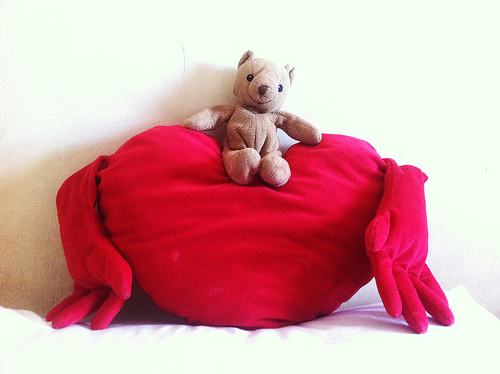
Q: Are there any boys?
A: No, there are no boys.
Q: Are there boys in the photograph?
A: No, there are no boys.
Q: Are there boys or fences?
A: No, there are no boys or fences.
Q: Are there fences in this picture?
A: No, there are no fences.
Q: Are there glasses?
A: No, there are no glasses.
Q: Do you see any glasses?
A: No, there are no glasses.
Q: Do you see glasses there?
A: No, there are no glasses.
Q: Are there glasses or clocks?
A: No, there are no glasses or clocks.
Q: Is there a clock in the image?
A: No, there are no clocks.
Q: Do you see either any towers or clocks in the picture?
A: No, there are no clocks or towers.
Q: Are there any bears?
A: Yes, there is a bear.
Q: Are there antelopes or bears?
A: Yes, there is a bear.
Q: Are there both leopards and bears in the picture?
A: No, there is a bear but no leopards.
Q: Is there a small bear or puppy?
A: Yes, there is a small bear.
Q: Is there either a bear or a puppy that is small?
A: Yes, the bear is small.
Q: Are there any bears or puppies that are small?
A: Yes, the bear is small.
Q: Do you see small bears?
A: Yes, there is a small bear.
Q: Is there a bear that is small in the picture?
A: Yes, there is a small bear.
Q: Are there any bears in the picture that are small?
A: Yes, there is a bear that is small.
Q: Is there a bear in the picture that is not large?
A: Yes, there is a small bear.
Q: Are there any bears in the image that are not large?
A: Yes, there is a small bear.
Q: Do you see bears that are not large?
A: Yes, there is a small bear.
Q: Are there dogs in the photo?
A: No, there are no dogs.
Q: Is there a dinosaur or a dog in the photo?
A: No, there are no dogs or dinosaurs.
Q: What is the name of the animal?
A: The animal is a bear.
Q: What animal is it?
A: The animal is a bear.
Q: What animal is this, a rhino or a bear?
A: That is a bear.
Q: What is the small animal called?
A: The animal is a bear.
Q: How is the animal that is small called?
A: The animal is a bear.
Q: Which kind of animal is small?
A: The animal is a bear.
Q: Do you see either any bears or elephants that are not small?
A: No, there is a bear but it is small.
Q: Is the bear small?
A: Yes, the bear is small.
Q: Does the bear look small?
A: Yes, the bear is small.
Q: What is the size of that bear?
A: The bear is small.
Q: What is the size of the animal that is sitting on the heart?
A: The bear is small.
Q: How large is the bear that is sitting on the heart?
A: The bear is small.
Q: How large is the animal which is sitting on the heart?
A: The bear is small.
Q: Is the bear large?
A: No, the bear is small.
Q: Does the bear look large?
A: No, the bear is small.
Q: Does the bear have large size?
A: No, the bear is small.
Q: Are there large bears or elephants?
A: No, there is a bear but it is small.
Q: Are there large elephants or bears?
A: No, there is a bear but it is small.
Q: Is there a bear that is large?
A: No, there is a bear but it is small.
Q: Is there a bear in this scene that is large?
A: No, there is a bear but it is small.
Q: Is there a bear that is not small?
A: No, there is a bear but it is small.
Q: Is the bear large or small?
A: The bear is small.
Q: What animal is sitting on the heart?
A: The bear is sitting on the heart.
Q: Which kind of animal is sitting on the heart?
A: The animal is a bear.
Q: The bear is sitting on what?
A: The bear is sitting on the heart.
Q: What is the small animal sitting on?
A: The bear is sitting on the heart.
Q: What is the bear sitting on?
A: The bear is sitting on the heart.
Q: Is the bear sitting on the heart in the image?
A: Yes, the bear is sitting on the heart.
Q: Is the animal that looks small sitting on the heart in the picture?
A: Yes, the bear is sitting on the heart.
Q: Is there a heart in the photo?
A: Yes, there is a heart.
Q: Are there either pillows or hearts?
A: Yes, there is a heart.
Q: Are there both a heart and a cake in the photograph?
A: No, there is a heart but no cakes.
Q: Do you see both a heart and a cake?
A: No, there is a heart but no cakes.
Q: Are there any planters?
A: No, there are no planters.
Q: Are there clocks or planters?
A: No, there are no planters or clocks.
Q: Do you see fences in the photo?
A: No, there are no fences.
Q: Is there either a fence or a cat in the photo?
A: No, there are no fences or cats.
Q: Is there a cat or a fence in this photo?
A: No, there are no fences or cats.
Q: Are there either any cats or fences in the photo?
A: No, there are no fences or cats.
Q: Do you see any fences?
A: No, there are no fences.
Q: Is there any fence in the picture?
A: No, there are no fences.